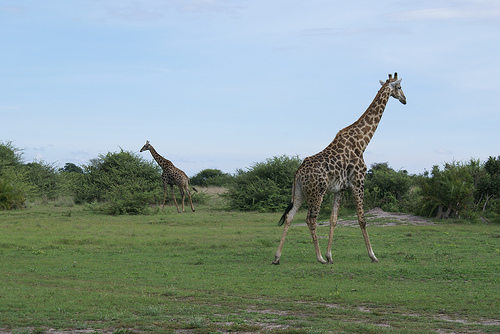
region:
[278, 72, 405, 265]
A tall giraffe walking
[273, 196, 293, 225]
A giraffe's black tail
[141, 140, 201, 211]
A smaller giraffe in the distance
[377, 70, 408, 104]
The head of the giraffe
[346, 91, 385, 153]
The long neck of the giraffe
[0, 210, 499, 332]
Patchy grass on the ground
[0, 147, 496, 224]
Bushes and shrubs around the clearing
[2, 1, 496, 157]
A blue cloudy sky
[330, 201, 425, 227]
Patches of dirt in the grass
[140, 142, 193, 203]
A giraffe facing the left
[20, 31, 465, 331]
picture taken outdoors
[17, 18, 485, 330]
picture taken during the day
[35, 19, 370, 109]
the sky doesn't have any clouds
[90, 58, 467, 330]
two giraffes walking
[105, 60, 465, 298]
the giraffes are on the plains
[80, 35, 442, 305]
the giraffes are on the grass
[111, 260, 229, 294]
the grass is cut short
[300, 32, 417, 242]
the giraffe has brown spots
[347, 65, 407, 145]
the giraffe has a long neck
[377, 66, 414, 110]
the giraffe has two ears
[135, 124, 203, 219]
giraffe standing near the bush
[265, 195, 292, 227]
black tip of the tail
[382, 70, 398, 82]
horns on the giraffes head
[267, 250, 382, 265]
hooves of the giraffe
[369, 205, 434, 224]
patches of dirt on the ground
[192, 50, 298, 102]
clear blue sunny day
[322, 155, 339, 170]
spots on the giraffe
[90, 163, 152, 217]
green bush near the giraffe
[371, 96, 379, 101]
mane of the giraffe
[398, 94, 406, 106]
mouth of the giraffe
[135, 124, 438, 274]
two giraffes on plain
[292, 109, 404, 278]
giraffe has long neck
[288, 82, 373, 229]
brown and orange spots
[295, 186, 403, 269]
giraffe has brown legs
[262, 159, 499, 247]
green bushes behind giraffe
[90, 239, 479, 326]
green grass on ground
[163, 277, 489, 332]
bare patches on ground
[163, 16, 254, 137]
blue and clear sky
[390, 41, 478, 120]
few thin clouds in sky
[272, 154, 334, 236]
giraffe has long tail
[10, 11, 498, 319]
picture taken outside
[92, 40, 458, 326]
giraffes on the plains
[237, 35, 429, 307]
the giraffe is brown with spots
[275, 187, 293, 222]
the giraffe has a black tail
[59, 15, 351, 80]
the sky is full of clouds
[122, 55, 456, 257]
the giraffes are tall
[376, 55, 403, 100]
the giraffe has two ears